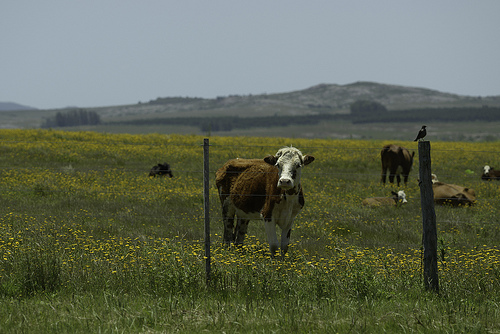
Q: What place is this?
A: It is a field.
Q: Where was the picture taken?
A: It was taken at the field.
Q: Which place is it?
A: It is a field.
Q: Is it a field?
A: Yes, it is a field.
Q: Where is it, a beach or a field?
A: It is a field.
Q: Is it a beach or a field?
A: It is a field.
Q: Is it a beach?
A: No, it is a field.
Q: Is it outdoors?
A: Yes, it is outdoors.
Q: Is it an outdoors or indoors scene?
A: It is outdoors.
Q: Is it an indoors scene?
A: No, it is outdoors.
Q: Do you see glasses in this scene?
A: No, there are no glasses.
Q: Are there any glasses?
A: No, there are no glasses.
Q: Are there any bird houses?
A: No, there are no bird houses.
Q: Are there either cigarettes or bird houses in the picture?
A: No, there are no bird houses or cigarettes.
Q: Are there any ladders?
A: No, there are no ladders.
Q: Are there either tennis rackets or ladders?
A: No, there are no ladders or tennis rackets.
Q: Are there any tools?
A: No, there are no tools.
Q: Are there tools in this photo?
A: No, there are no tools.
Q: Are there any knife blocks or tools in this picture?
A: No, there are no tools or knife blocks.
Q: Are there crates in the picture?
A: No, there are no crates.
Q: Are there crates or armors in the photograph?
A: No, there are no crates or armors.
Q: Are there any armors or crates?
A: No, there are no crates or armors.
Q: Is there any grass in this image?
A: Yes, there is grass.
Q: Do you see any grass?
A: Yes, there is grass.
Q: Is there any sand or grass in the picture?
A: Yes, there is grass.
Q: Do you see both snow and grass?
A: No, there is grass but no snow.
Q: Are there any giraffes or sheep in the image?
A: No, there are no giraffes or sheep.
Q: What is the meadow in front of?
A: The meadow is in front of the hill.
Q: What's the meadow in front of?
A: The meadow is in front of the hill.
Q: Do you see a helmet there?
A: No, there are no helmets.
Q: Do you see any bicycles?
A: No, there are no bicycles.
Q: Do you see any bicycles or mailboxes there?
A: No, there are no bicycles or mailboxes.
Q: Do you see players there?
A: No, there are no players.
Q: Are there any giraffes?
A: No, there are no giraffes.